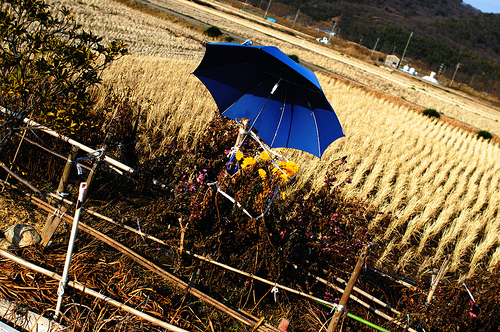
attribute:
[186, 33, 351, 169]
umbrella — blue, bright, cheerful, open, large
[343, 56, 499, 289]
crops — brown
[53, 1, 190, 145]
crops — brown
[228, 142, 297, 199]
flowers — yellow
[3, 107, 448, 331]
fence — rickety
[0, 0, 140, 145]
plant — green, small, spindly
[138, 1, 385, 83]
road — grey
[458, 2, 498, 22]
sky — blue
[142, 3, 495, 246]
field — tan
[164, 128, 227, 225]
flowers — pink, small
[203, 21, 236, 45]
shrubs — green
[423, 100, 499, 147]
shrubs — green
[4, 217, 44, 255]
rock — small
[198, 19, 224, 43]
bush — green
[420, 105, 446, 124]
bush — green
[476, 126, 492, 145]
bush — green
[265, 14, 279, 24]
building — blue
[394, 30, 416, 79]
electrical pole — tall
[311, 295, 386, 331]
pole — green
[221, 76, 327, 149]
spokes — metal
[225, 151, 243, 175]
handle — blue